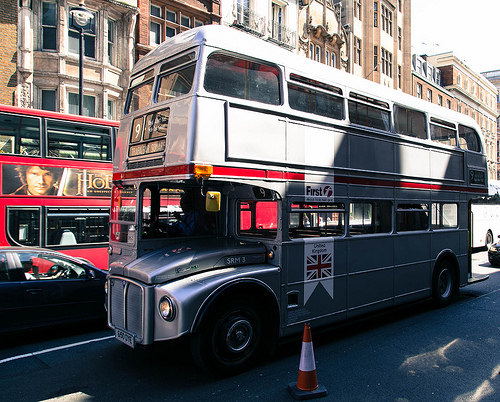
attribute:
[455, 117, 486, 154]
window — small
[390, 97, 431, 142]
window — small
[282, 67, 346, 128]
window — small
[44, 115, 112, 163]
window — small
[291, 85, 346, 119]
window — small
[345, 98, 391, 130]
window — small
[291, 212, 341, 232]
window — small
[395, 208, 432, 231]
window — small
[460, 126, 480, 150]
window — small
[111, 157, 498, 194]
stripe — red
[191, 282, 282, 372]
wheel — black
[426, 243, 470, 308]
wheel — black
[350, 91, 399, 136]
window — small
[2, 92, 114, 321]
bus — large, red, two-story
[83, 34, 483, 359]
bus — silver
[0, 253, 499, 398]
road — dark grey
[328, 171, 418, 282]
window — small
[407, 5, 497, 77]
sky — grey, bright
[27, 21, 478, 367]
bus — double decker, white, silver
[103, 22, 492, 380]
bus — large, white, two-story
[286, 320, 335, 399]
cone — red, white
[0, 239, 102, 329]
car — black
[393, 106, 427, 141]
window — small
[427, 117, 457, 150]
window — small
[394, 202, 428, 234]
window — small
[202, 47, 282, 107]
window — small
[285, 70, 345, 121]
window — small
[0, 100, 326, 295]
bus — red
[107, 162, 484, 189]
stripe — red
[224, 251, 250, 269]
number — white